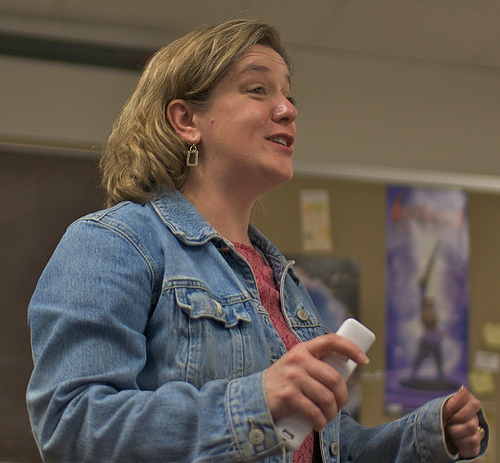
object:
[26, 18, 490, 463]
woman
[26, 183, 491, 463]
jacket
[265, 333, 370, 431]
hand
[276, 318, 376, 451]
remote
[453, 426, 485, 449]
finger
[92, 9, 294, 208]
hair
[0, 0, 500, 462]
room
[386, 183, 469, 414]
poster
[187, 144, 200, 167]
earring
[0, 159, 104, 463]
doorway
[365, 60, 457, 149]
wall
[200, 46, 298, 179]
face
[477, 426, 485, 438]
ring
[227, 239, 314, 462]
shirt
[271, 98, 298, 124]
nose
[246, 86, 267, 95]
eye